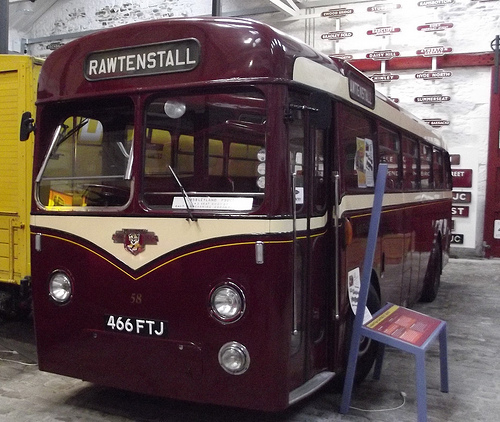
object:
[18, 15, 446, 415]
car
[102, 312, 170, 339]
numbers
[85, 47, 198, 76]
letters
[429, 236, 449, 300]
tire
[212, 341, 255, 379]
headlights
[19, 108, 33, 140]
mirror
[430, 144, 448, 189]
ground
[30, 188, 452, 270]
stripe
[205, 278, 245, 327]
headlight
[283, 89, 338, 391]
door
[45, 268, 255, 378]
headlights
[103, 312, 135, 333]
numbers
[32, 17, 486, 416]
bus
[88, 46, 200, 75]
sign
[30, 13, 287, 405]
bus front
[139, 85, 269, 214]
front window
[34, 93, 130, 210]
front window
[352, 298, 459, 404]
item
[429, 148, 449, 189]
windows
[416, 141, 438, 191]
windows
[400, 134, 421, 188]
windows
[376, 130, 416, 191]
windows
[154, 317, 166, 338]
letter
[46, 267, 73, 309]
headlight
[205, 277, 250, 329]
headlight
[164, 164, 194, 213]
wiper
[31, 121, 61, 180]
wiper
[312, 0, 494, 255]
wall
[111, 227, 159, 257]
symbol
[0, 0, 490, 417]
garage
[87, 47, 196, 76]
title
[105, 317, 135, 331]
numbers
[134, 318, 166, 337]
letters